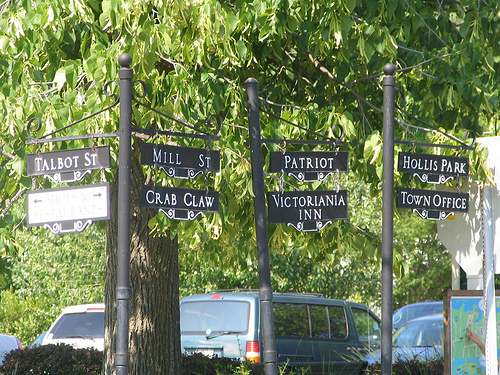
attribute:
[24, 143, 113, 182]
sign — black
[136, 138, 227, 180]
sign — black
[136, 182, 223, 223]
sign — black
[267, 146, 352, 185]
sign — black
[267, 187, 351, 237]
sign — black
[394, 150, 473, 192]
sign — black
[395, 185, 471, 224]
sign — black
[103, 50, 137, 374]
pole — black, iron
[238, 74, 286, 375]
pole — iron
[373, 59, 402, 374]
pole — iron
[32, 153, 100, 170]
writing — white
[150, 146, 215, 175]
writing — white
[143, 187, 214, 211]
writing — white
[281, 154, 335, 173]
writing — white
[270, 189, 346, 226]
writing — white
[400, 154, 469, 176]
writing — white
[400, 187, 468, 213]
writing — white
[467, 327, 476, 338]
finger — pointing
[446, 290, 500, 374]
map — area, directional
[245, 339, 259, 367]
tail light — red, white, yellow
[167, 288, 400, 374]
car — large, blue, parked, bluish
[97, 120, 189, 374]
trunk — tree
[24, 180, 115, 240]
sign — white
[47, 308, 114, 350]
window — rear